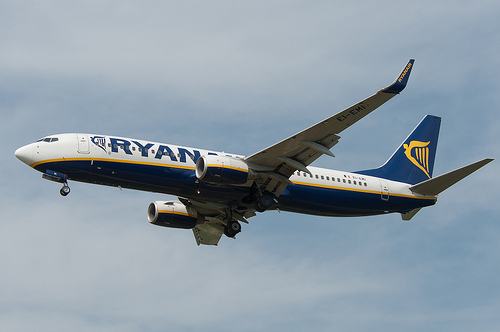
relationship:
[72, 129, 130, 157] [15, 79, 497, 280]
window on plane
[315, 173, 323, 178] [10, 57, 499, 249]
small window on airplane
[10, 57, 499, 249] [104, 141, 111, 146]
airplane has window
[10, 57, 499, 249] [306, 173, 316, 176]
airplane has window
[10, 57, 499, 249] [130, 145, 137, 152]
airplane has window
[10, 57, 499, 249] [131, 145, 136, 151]
airplane has window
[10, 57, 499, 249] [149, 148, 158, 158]
airplane has window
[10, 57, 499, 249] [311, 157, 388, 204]
airplane has window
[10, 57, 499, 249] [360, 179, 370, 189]
airplane has window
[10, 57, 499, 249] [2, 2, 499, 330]
airplane in sky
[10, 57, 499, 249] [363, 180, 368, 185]
airplane has window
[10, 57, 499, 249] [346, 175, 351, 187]
airplane has window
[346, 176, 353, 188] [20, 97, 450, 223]
glass window on airplane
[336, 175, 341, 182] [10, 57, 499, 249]
window on airplane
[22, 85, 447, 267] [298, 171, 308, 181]
airplane has glass window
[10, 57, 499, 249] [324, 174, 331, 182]
airplane has small window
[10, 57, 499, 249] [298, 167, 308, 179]
airplane has window